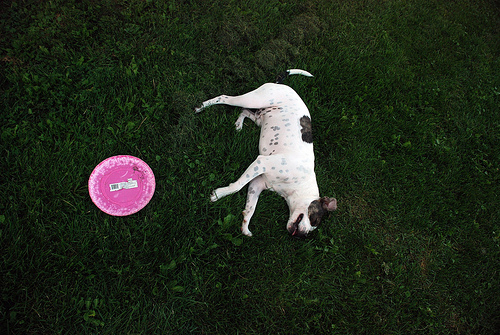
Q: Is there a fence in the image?
A: No, there are no fences.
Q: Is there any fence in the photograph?
A: No, there are no fences.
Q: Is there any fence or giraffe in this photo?
A: No, there are no fences or giraffes.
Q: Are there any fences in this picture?
A: No, there are no fences.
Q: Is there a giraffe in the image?
A: No, there are no giraffes.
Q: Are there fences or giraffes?
A: No, there are no giraffes or fences.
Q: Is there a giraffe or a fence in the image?
A: No, there are no giraffes or fences.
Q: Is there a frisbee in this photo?
A: Yes, there is a frisbee.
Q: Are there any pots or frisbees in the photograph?
A: Yes, there is a frisbee.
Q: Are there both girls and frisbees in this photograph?
A: No, there is a frisbee but no girls.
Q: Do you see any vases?
A: No, there are no vases.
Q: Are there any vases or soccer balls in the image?
A: No, there are no vases or soccer balls.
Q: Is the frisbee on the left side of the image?
A: Yes, the frisbee is on the left of the image.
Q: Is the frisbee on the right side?
A: No, the frisbee is on the left of the image.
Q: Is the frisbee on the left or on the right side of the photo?
A: The frisbee is on the left of the image.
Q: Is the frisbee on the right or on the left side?
A: The frisbee is on the left of the image.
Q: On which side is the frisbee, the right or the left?
A: The frisbee is on the left of the image.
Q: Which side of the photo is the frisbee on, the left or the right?
A: The frisbee is on the left of the image.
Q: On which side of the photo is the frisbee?
A: The frisbee is on the left of the image.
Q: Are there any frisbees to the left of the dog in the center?
A: Yes, there is a frisbee to the left of the dog.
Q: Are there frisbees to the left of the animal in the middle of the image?
A: Yes, there is a frisbee to the left of the dog.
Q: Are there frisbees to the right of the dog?
A: No, the frisbee is to the left of the dog.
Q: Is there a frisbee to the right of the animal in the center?
A: No, the frisbee is to the left of the dog.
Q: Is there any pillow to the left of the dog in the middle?
A: No, there is a frisbee to the left of the dog.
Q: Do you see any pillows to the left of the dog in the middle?
A: No, there is a frisbee to the left of the dog.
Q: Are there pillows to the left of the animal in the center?
A: No, there is a frisbee to the left of the dog.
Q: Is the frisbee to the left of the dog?
A: Yes, the frisbee is to the left of the dog.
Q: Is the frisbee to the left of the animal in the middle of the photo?
A: Yes, the frisbee is to the left of the dog.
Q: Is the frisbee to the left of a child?
A: No, the frisbee is to the left of the dog.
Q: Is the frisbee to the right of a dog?
A: No, the frisbee is to the left of a dog.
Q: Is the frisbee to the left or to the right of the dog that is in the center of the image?
A: The frisbee is to the left of the dog.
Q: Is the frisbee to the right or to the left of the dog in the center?
A: The frisbee is to the left of the dog.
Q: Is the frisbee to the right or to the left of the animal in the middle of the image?
A: The frisbee is to the left of the dog.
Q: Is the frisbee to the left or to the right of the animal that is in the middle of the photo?
A: The frisbee is to the left of the dog.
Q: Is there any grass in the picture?
A: Yes, there is grass.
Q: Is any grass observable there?
A: Yes, there is grass.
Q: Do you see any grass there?
A: Yes, there is grass.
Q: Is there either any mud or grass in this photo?
A: Yes, there is grass.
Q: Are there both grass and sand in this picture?
A: No, there is grass but no sand.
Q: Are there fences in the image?
A: No, there are no fences.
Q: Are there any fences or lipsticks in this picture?
A: No, there are no fences or lipsticks.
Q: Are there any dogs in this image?
A: Yes, there is a dog.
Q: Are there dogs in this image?
A: Yes, there is a dog.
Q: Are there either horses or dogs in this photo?
A: Yes, there is a dog.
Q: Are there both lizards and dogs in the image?
A: No, there is a dog but no lizards.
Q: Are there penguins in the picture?
A: No, there are no penguins.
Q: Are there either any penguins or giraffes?
A: No, there are no penguins or giraffes.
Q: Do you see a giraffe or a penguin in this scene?
A: No, there are no penguins or giraffes.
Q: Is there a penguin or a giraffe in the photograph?
A: No, there are no penguins or giraffes.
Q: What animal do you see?
A: The animal is a dog.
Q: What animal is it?
A: The animal is a dog.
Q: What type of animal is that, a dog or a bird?
A: This is a dog.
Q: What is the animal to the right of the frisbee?
A: The animal is a dog.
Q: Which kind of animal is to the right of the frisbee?
A: The animal is a dog.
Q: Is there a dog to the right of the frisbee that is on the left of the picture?
A: Yes, there is a dog to the right of the frisbee.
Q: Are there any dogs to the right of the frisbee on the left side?
A: Yes, there is a dog to the right of the frisbee.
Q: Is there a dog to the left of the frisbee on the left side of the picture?
A: No, the dog is to the right of the frisbee.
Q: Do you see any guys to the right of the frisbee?
A: No, there is a dog to the right of the frisbee.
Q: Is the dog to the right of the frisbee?
A: Yes, the dog is to the right of the frisbee.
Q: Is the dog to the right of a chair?
A: No, the dog is to the right of the frisbee.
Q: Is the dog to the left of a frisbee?
A: No, the dog is to the right of a frisbee.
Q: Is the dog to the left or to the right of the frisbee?
A: The dog is to the right of the frisbee.